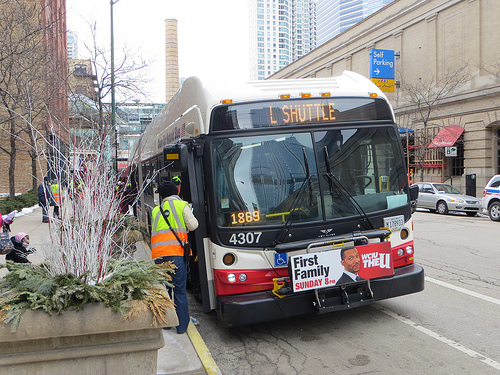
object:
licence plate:
[384, 215, 409, 234]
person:
[146, 171, 202, 333]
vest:
[144, 199, 192, 263]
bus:
[118, 70, 425, 332]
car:
[405, 176, 482, 218]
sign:
[269, 251, 288, 269]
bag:
[158, 200, 195, 262]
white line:
[421, 269, 498, 311]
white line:
[370, 296, 495, 371]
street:
[185, 209, 497, 371]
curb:
[185, 318, 225, 373]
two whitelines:
[370, 272, 499, 374]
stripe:
[373, 302, 498, 369]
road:
[185, 211, 497, 373]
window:
[213, 122, 410, 233]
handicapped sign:
[272, 250, 287, 269]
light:
[266, 101, 340, 123]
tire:
[430, 199, 452, 221]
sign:
[370, 47, 396, 77]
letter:
[371, 49, 394, 70]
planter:
[0, 253, 168, 375]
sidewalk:
[0, 197, 160, 283]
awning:
[425, 123, 467, 150]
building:
[263, 0, 498, 214]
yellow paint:
[186, 318, 223, 373]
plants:
[0, 89, 179, 330]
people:
[39, 171, 62, 229]